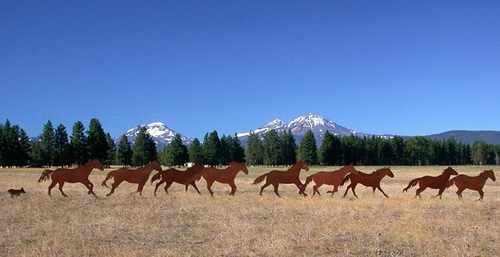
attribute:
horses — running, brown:
[38, 159, 496, 199]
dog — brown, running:
[6, 187, 27, 198]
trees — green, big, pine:
[0, 119, 500, 169]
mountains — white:
[18, 113, 500, 149]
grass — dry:
[0, 163, 500, 256]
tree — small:
[189, 137, 204, 166]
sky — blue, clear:
[0, 0, 500, 141]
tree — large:
[88, 118, 111, 168]